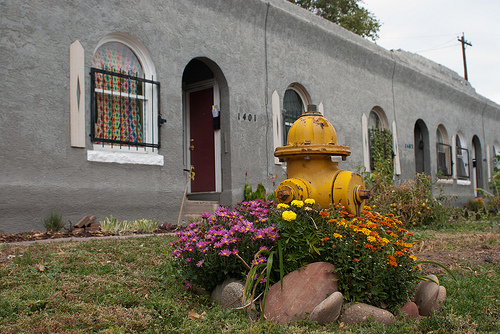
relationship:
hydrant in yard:
[271, 102, 374, 221] [1, 206, 499, 332]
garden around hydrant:
[166, 194, 447, 332] [271, 102, 374, 221]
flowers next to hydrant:
[168, 197, 284, 325] [271, 102, 374, 221]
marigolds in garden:
[272, 196, 324, 275] [166, 194, 447, 332]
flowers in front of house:
[275, 194, 459, 333] [0, 1, 499, 243]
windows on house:
[85, 29, 499, 189] [0, 1, 499, 243]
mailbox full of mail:
[209, 110, 225, 133] [209, 102, 221, 121]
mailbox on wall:
[209, 110, 225, 133] [183, 55, 231, 209]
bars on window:
[86, 64, 170, 154] [85, 30, 167, 169]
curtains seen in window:
[91, 40, 146, 148] [85, 30, 167, 169]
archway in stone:
[179, 53, 237, 228] [0, 1, 499, 243]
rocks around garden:
[208, 258, 449, 334] [166, 194, 447, 332]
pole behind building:
[455, 32, 474, 85] [0, 1, 499, 243]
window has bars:
[85, 30, 167, 169] [86, 64, 170, 154]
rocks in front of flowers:
[208, 258, 449, 334] [166, 197, 456, 322]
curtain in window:
[91, 40, 146, 148] [85, 30, 167, 169]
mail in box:
[209, 102, 221, 121] [209, 110, 225, 133]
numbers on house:
[236, 110, 259, 124] [0, 1, 499, 243]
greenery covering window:
[367, 125, 397, 178] [362, 104, 397, 178]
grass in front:
[1, 206, 499, 332] [1, 2, 497, 333]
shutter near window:
[63, 38, 493, 185] [85, 29, 499, 189]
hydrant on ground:
[271, 102, 374, 221] [1, 206, 499, 332]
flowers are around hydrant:
[166, 197, 456, 322] [271, 102, 374, 221]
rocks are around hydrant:
[208, 258, 449, 334] [271, 102, 374, 221]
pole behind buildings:
[455, 32, 474, 85] [0, 1, 499, 243]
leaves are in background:
[287, 0, 385, 45] [288, 1, 499, 109]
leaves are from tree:
[287, 0, 385, 45] [282, 0, 383, 45]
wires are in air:
[418, 31, 499, 58] [357, 1, 499, 109]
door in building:
[187, 85, 219, 194] [0, 1, 499, 243]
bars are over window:
[86, 64, 170, 154] [85, 30, 167, 169]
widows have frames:
[85, 29, 499, 189] [67, 32, 498, 186]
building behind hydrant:
[0, 1, 499, 243] [271, 102, 374, 221]